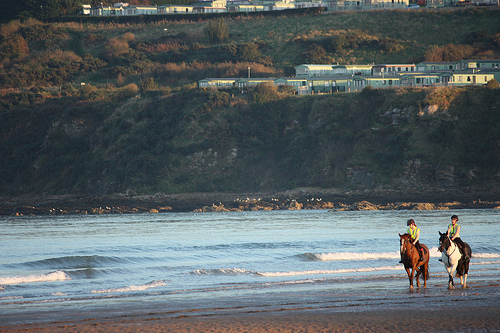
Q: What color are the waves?
A: Blue and white.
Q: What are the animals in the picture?
A: Horses.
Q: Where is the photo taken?
A: Beach.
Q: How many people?
A: Two.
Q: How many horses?
A: Two.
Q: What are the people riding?
A: Horses.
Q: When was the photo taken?
A: Morning.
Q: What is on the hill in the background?
A: Buildings.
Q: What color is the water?
A: Blue.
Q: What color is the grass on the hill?
A: Brown.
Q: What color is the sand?
A: Brown.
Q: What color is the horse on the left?
A: Brown.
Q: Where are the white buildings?
A: On the cliff.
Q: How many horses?
A: 2.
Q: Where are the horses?
A: On the beach.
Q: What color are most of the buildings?
A: White.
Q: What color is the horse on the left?
A: Brown.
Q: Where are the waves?
A: Beside the horses.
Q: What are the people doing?
A: Riding horses.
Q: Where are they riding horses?
A: The beach.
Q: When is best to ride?
A: Daytime.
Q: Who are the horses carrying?
A: The people.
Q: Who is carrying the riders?
A: The horses.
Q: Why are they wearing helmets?
A: Head protection.